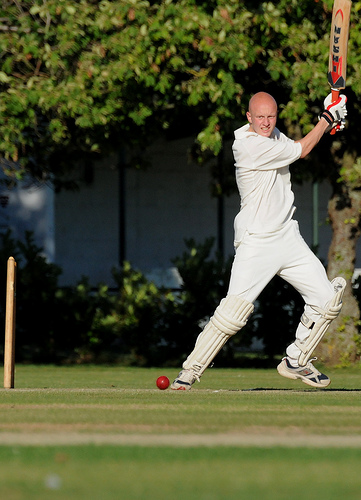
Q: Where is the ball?
A: On the ground.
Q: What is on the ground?
A: The ball.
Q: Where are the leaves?
A: On the tree.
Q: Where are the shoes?
A: On the man's feet.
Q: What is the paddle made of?
A: Wood.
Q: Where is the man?
A: On a field.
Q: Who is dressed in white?
A: The player.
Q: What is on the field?
A: Green grass.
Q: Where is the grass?
A: Below the man.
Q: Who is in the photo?
A: A man.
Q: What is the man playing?
A: Cricket.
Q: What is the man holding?
A: A piece of wood.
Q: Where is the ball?
A: On the ground.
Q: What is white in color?
A: Man's outfit.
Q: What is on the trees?
A: Leaves.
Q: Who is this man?
A: A cricket player.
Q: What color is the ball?
A: Red.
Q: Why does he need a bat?
A: To hit the ball.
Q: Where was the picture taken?
A: A cricket game.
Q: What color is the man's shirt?
A: White.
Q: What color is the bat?
A: Brown, black, and red.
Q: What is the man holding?
A: A bat.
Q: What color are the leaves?
A: Green.